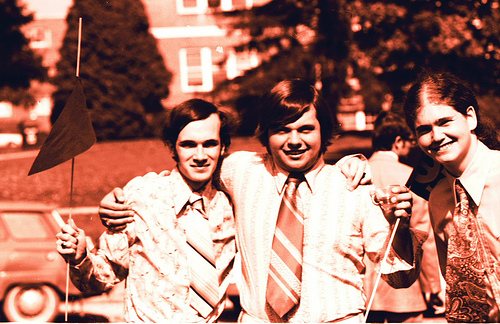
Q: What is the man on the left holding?
A: A flag.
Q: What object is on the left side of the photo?
A: A car.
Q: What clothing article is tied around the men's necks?
A: Ties.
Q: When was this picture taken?
A: In the 1970's.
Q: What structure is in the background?
A: A house.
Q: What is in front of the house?
A: A tree.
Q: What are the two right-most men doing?
A: Smiling.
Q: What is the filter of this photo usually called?
A: Sepia.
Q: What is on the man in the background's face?
A: Glasses.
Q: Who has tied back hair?
A: The guy to the right.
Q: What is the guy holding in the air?
A: A black flag.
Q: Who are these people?
A: A group of men.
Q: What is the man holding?
A: A flag.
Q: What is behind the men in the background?
A: Trees.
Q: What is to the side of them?
A: A parked car.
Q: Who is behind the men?
A: A man.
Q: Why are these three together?
A: Having fun.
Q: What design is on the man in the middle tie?
A: Stripes.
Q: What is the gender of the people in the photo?
A: Male.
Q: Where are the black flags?
A: Men's hands.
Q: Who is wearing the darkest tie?
A: Middle man.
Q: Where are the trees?
A: Background.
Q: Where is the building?
A: Behind the trees.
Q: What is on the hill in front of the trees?
A: Grass.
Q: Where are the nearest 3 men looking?
A: At camera.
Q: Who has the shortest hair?
A: Man on left.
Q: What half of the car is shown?
A: Half.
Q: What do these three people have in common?
A: Wearing ties.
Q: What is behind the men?
A: A tall tree.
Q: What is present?
A: People.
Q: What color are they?
A: White.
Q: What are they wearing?
A: Clothes.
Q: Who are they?
A: Friends.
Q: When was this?
A: Daytime.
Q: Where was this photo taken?
A: Near building.